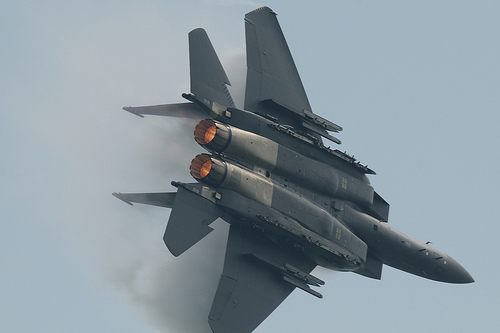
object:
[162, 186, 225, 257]
tail wing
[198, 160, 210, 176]
light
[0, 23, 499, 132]
background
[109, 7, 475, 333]
black jet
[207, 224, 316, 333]
wing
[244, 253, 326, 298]
weapon system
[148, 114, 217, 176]
smoke emisison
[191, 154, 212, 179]
hole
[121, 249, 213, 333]
smoke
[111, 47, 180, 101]
smoke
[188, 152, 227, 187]
engines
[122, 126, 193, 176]
cloud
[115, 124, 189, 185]
smoke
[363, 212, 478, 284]
body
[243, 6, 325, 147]
ribbed wings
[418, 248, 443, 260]
tiny curls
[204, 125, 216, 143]
lights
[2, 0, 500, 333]
sky